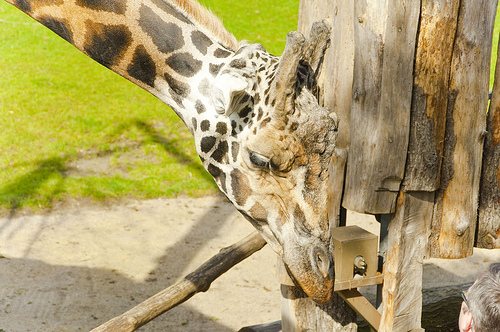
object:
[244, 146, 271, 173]
eye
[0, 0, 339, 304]
giraffe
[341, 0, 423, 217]
bar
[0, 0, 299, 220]
grass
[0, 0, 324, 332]
ground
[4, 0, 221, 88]
neck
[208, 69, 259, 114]
ears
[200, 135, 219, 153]
spots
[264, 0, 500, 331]
fence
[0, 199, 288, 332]
sand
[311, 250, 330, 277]
nostril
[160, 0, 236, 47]
mane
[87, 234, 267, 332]
stick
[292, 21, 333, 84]
horns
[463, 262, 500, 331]
hair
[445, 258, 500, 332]
man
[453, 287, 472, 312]
glasses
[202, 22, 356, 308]
head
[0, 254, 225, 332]
shadow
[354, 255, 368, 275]
bolt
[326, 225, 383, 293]
lock